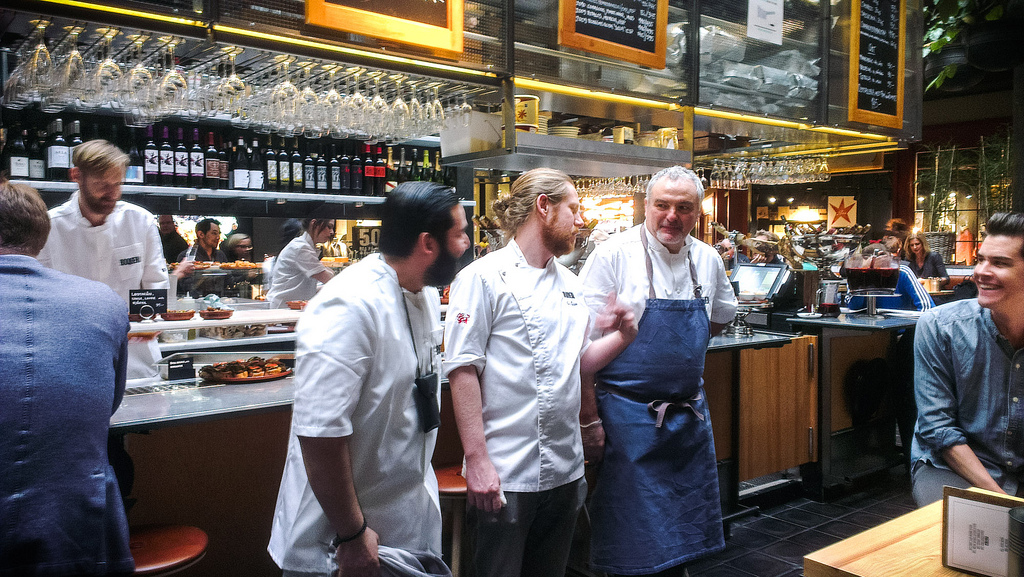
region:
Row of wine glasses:
[2, 6, 508, 152]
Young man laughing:
[908, 204, 1023, 498]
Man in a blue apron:
[577, 159, 749, 575]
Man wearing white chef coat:
[434, 166, 644, 575]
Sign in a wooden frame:
[842, 1, 913, 137]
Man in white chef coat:
[32, 137, 176, 315]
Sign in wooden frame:
[555, 1, 672, 78]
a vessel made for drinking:
[24, 22, 62, 90]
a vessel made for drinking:
[57, 19, 92, 92]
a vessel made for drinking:
[103, 23, 123, 94]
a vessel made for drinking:
[120, 23, 153, 96]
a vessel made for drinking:
[155, 32, 184, 97]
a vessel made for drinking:
[201, 42, 221, 104]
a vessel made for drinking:
[223, 42, 239, 99]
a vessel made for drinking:
[268, 51, 298, 128]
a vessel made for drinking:
[332, 54, 359, 124]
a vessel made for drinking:
[356, 67, 389, 138]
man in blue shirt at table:
[896, 192, 1021, 522]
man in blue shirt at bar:
[6, 173, 140, 563]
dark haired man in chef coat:
[261, 178, 487, 575]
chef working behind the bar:
[31, 134, 177, 349]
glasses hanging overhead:
[11, 3, 501, 152]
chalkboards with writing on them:
[290, 0, 951, 137]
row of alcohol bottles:
[6, 100, 491, 195]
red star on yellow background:
[808, 191, 876, 236]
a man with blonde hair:
[496, 177, 569, 225]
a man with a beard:
[415, 234, 467, 293]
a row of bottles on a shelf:
[149, 134, 347, 186]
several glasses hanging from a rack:
[79, 45, 479, 118]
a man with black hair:
[370, 169, 466, 245]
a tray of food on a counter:
[199, 346, 294, 391]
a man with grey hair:
[643, 158, 705, 203]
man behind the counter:
[48, 136, 178, 329]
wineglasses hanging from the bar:
[21, 16, 481, 176]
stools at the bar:
[124, 437, 537, 570]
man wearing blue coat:
[0, 177, 169, 573]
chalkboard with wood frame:
[557, 1, 679, 71]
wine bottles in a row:
[0, 99, 449, 204]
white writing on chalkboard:
[581, 3, 658, 41]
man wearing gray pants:
[470, 159, 607, 574]